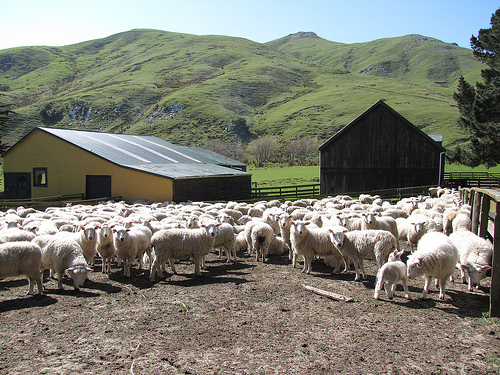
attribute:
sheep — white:
[0, 199, 489, 299]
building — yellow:
[3, 124, 253, 208]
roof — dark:
[37, 126, 249, 177]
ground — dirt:
[200, 288, 412, 374]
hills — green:
[0, 28, 499, 160]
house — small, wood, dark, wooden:
[318, 100, 447, 199]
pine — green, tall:
[445, 8, 499, 169]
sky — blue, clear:
[2, 1, 500, 54]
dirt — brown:
[3, 294, 498, 372]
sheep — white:
[55, 226, 152, 277]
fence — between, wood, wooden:
[244, 181, 329, 203]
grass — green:
[117, 27, 164, 47]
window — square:
[31, 163, 50, 189]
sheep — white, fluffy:
[407, 228, 459, 306]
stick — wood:
[470, 187, 499, 206]